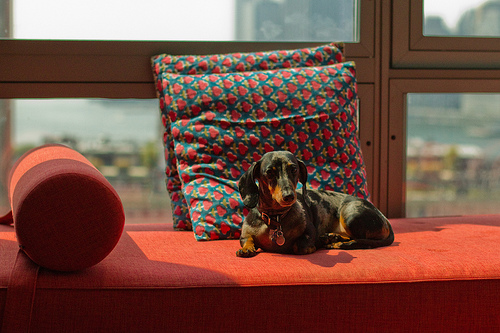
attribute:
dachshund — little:
[228, 152, 402, 272]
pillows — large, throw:
[145, 39, 400, 250]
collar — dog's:
[258, 202, 295, 244]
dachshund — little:
[221, 150, 428, 280]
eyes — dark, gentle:
[250, 157, 291, 179]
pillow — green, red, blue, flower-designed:
[155, 54, 382, 244]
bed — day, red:
[1, 146, 498, 329]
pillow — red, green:
[6, 143, 125, 273]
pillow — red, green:
[150, 41, 373, 242]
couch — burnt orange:
[18, 109, 498, 311]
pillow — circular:
[6, 139, 132, 279]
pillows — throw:
[157, 50, 360, 242]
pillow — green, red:
[146, 30, 350, 214]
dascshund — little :
[234, 150, 394, 257]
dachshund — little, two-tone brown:
[237, 150, 394, 257]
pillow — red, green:
[183, 70, 212, 118]